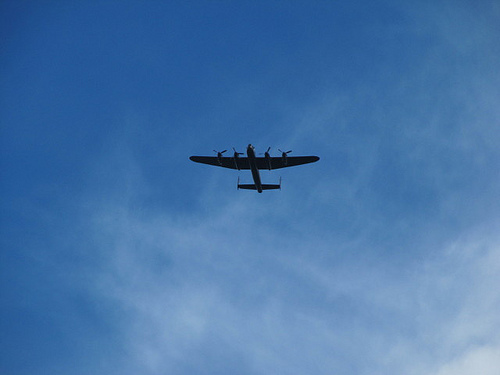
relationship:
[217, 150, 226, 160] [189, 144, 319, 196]
engine on plane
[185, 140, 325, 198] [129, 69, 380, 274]
aircraft in sky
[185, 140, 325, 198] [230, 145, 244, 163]
aircraft with propeller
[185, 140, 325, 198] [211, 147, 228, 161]
aircraft with propeller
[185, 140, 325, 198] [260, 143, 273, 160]
aircraft with propeller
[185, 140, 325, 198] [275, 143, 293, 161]
aircraft with propeller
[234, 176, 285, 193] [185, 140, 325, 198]
back tail of aircraft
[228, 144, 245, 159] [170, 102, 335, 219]
propeller on airplane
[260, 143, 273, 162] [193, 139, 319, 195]
propeller on airplane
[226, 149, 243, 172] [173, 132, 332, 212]
engine on plane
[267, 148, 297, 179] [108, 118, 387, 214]
engine on plane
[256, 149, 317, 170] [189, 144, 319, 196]
wing on plane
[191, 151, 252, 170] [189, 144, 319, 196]
wing on plane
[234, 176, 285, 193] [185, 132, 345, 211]
back tail on plane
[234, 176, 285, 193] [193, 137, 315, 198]
back tail on jet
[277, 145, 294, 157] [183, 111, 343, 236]
propeller on jet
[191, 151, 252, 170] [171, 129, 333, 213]
wing on jet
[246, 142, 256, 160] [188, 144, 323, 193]
nose on airplane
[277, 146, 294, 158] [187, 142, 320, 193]
propeller on aircraft